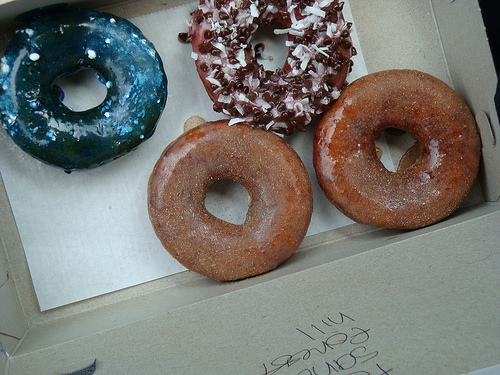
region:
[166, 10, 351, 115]
There is coconut on the doughnut.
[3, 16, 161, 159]
There is a blue doughnut.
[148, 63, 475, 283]
There are two glazed doughnuts.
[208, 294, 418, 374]
There is writing on the box.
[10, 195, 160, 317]
There is a piece of paper under the doughnuts.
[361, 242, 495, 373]
The doughnuts are in a box.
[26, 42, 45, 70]
There are white specks on the doughnut.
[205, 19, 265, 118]
There are chocolate pieces on the doughnut.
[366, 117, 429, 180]
There is glaze on the box from the box.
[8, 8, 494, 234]
All of the doughnuts have holes.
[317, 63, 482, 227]
glazed donut on bottom right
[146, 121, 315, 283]
glazed donut in center of picture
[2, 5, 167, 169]
dark glazed donut in top left of box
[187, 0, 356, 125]
red donut with coconut on top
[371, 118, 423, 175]
hole of glazed donut on right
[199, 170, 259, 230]
hole of glazed donut in center of picture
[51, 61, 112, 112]
hole of dark glazed donut on left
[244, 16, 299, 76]
hole of donut with coconut on top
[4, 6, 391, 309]
white paper under donuts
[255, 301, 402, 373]
writing on lid of box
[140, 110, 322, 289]
Donut is brown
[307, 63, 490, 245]
Donut is brown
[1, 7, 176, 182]
Donut is blue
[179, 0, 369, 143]
Donut has coconut on top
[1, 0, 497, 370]
Donut is in a box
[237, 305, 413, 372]
Letters writing over box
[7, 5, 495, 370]
Box is open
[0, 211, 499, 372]
Flap of box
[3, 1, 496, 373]
Box inside is color tan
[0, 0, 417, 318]
Donut are over a white paper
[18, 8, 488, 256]
box with four doughnuts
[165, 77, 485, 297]
two glazed doughnuts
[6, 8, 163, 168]
blueberry glazed doughnut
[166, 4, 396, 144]
doughnut with coconut sprinkles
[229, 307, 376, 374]
hand writing on doughnut box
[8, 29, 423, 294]
parchment paper under doughnuts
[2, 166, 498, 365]
doughnuts in cardboard box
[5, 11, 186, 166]
blue doughnut with clear glaze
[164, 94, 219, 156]
glaze draining off of doughnut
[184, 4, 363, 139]
chocolate and coconut sprinkles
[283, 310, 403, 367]
writings on white paper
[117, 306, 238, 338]
edge of donut box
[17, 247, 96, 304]
white liner in donut box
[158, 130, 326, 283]
large brown glaze donut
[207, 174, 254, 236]
hole in glaze donut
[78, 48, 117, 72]
small white sprinkle on blue donut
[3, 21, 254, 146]
shiny blue donut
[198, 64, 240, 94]
white sprinkle on donut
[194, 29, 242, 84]
chocolate chip sprinkles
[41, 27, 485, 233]
box full of different color donuts